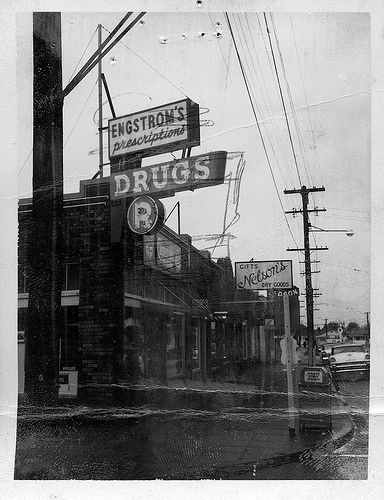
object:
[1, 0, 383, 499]
photograph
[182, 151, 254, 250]
drawing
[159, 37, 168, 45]
hole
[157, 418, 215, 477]
fingerprint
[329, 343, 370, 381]
car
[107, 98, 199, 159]
sign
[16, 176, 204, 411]
building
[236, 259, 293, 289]
sign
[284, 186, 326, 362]
pole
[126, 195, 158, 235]
sign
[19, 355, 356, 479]
sidewalk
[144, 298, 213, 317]
awning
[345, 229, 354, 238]
light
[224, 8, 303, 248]
wire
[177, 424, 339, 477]
curb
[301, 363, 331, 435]
container